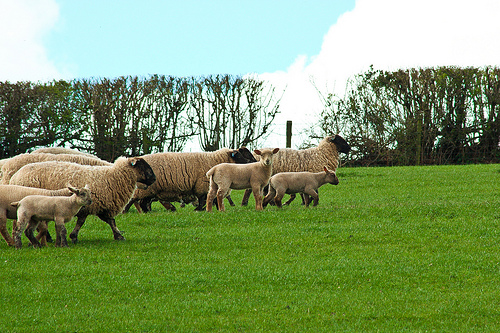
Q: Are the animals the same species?
A: Yes, all the animals are sheep.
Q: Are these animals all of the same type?
A: Yes, all the animals are sheep.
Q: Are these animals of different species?
A: No, all the animals are sheep.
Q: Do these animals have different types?
A: No, all the animals are sheep.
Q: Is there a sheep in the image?
A: Yes, there is a sheep.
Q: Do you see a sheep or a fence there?
A: Yes, there is a sheep.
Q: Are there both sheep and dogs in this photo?
A: No, there is a sheep but no dogs.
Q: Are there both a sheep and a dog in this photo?
A: No, there is a sheep but no dogs.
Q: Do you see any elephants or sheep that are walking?
A: Yes, the sheep is walking.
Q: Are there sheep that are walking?
A: Yes, there is a sheep that is walking.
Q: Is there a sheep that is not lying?
A: Yes, there is a sheep that is walking.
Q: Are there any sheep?
A: Yes, there is a sheep.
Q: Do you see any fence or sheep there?
A: Yes, there is a sheep.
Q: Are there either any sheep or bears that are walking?
A: Yes, the sheep is walking.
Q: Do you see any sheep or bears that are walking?
A: Yes, the sheep is walking.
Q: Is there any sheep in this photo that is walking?
A: Yes, there is a sheep that is walking.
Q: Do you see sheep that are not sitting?
A: Yes, there is a sheep that is walking .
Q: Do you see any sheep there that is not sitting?
A: Yes, there is a sheep that is walking .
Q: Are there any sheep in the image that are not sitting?
A: Yes, there is a sheep that is walking.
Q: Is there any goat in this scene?
A: No, there are no goats.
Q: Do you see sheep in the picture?
A: Yes, there is a sheep.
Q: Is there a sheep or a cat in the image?
A: Yes, there is a sheep.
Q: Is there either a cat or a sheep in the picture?
A: Yes, there is a sheep.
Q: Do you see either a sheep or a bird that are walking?
A: Yes, the sheep is walking.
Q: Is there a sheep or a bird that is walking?
A: Yes, the sheep is walking.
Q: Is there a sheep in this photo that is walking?
A: Yes, there is a sheep that is walking.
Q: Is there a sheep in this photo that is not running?
A: Yes, there is a sheep that is walking.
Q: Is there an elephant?
A: No, there are no elephants.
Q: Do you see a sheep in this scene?
A: Yes, there is a sheep.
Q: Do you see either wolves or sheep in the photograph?
A: Yes, there is a sheep.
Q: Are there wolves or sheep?
A: Yes, there is a sheep.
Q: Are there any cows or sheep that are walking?
A: Yes, the sheep is walking.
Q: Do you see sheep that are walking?
A: Yes, there is a sheep that is walking.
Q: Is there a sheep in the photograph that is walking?
A: Yes, there is a sheep that is walking.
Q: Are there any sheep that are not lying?
A: Yes, there is a sheep that is walking.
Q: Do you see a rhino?
A: No, there are no rhinos.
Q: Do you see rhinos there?
A: No, there are no rhinos.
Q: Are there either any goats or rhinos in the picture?
A: No, there are no rhinos or goats.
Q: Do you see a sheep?
A: Yes, there is a sheep.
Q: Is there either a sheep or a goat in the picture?
A: Yes, there is a sheep.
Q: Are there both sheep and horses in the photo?
A: No, there is a sheep but no horses.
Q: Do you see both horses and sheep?
A: No, there is a sheep but no horses.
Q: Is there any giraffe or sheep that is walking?
A: Yes, the sheep is walking.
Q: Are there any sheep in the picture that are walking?
A: Yes, there is a sheep that is walking.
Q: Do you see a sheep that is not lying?
A: Yes, there is a sheep that is walking .